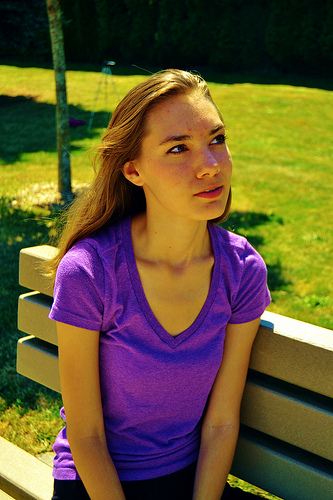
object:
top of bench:
[19, 243, 333, 398]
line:
[151, 224, 206, 239]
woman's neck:
[143, 186, 207, 251]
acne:
[187, 127, 191, 131]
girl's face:
[136, 95, 233, 220]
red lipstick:
[193, 181, 223, 198]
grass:
[0, 61, 332, 498]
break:
[113, 318, 232, 365]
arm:
[56, 321, 125, 499]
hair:
[35, 69, 231, 291]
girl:
[35, 67, 271, 499]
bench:
[0, 244, 332, 500]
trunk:
[47, 0, 71, 193]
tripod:
[87, 61, 120, 132]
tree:
[264, 0, 333, 91]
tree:
[210, 0, 268, 73]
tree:
[145, 0, 213, 64]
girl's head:
[121, 70, 233, 222]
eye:
[165, 143, 190, 154]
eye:
[209, 133, 228, 145]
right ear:
[121, 160, 145, 186]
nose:
[195, 144, 220, 179]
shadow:
[0, 193, 295, 413]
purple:
[48, 221, 271, 482]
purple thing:
[68, 118, 85, 127]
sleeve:
[48, 240, 103, 331]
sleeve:
[228, 231, 272, 325]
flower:
[11, 200, 17, 208]